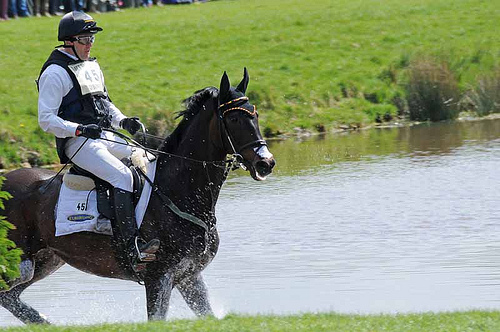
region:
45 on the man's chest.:
[68, 66, 111, 97]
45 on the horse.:
[65, 198, 99, 221]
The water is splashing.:
[144, 272, 224, 317]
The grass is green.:
[326, 314, 428, 331]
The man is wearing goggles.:
[55, 33, 112, 60]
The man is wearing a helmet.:
[57, 11, 101, 40]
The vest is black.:
[63, 95, 106, 115]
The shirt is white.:
[36, 86, 70, 108]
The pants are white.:
[81, 137, 124, 170]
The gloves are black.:
[80, 114, 146, 156]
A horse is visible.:
[155, 64, 363, 315]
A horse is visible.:
[115, 24, 226, 304]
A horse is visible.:
[172, 55, 240, 216]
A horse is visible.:
[161, 97, 279, 238]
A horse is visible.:
[182, 94, 292, 326]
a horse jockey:
[38, 10, 157, 273]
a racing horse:
[0, 65, 272, 324]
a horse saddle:
[50, 150, 150, 217]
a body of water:
[318, 152, 440, 246]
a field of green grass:
[251, 15, 361, 71]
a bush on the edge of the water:
[398, 52, 468, 118]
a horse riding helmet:
[52, 6, 103, 37]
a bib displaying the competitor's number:
[65, 52, 110, 97]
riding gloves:
[77, 116, 138, 137]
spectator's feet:
[6, 0, 186, 14]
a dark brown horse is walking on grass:
[2, 73, 282, 330]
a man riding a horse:
[28, 5, 169, 285]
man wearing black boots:
[105, 178, 140, 273]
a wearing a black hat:
[30, 5, 172, 286]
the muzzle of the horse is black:
[241, 141, 279, 183]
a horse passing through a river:
[238, 113, 493, 308]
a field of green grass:
[121, 2, 496, 72]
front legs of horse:
[133, 278, 228, 326]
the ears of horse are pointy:
[210, 53, 255, 98]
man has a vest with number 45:
[30, 6, 170, 271]